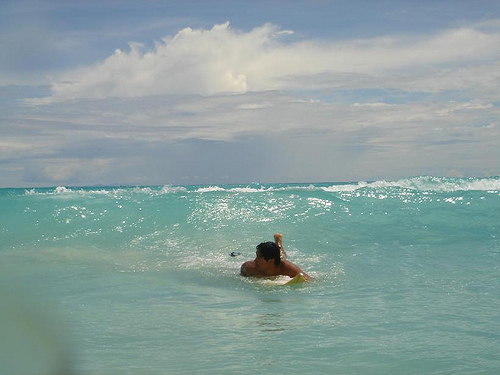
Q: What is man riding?
A: Surfboard.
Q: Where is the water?
A: Ocean.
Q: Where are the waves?
A: In ocean.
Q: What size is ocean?
A: Big.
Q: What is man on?
A: Belly.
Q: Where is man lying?
A: On board.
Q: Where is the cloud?
A: In sky.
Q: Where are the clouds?
A: In sky.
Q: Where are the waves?
A: In water.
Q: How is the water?
A: Calm.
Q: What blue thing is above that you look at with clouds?
A: Sky.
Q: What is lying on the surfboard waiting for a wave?
A: A man.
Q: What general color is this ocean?
A: Blue.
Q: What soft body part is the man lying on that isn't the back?
A: Stomach.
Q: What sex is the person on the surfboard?
A: Male.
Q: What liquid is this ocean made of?
A: Water.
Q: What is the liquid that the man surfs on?
A: Water.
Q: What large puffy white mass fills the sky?
A: Clouds.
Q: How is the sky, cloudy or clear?
A: Cloudy.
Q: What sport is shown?
A: Surfing.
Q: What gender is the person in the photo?
A: Male.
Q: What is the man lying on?
A: Surfboard.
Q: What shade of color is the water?
A: Turquoise.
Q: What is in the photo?
A: A man.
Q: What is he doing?
A: Surfing.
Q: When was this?
A: Daytime.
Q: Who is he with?
A: Nobody.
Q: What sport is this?
A: Surfing.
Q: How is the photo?
A: Clear.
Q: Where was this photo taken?
A: The ocean.